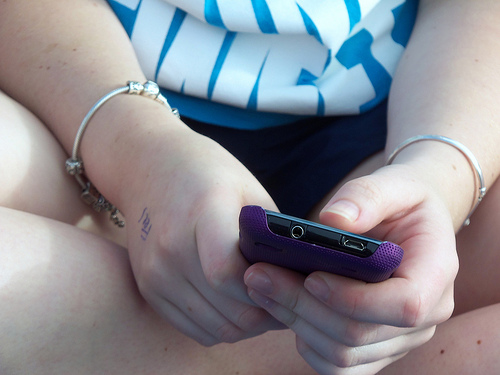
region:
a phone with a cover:
[219, 187, 411, 336]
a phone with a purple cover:
[247, 184, 426, 348]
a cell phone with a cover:
[237, 158, 447, 347]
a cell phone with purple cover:
[211, 177, 401, 322]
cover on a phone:
[232, 191, 462, 351]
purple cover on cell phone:
[232, 160, 468, 374]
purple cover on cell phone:
[229, 197, 410, 307]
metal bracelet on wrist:
[385, 115, 486, 239]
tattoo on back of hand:
[134, 202, 164, 248]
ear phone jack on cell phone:
[284, 220, 308, 242]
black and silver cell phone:
[228, 181, 411, 298]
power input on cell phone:
[338, 230, 370, 257]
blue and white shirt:
[108, 0, 427, 144]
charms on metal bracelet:
[118, 67, 170, 109]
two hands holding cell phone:
[77, 93, 490, 372]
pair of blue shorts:
[171, 96, 418, 245]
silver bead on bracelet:
[156, 93, 168, 105]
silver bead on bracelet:
[141, 78, 159, 97]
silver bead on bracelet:
[125, 78, 142, 93]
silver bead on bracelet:
[66, 158, 81, 175]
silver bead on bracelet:
[76, 186, 103, 211]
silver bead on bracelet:
[95, 198, 107, 212]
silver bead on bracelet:
[476, 187, 486, 204]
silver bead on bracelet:
[463, 218, 471, 226]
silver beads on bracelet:
[125, 75, 167, 102]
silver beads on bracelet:
[66, 156, 106, 213]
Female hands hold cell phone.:
[134, 119, 439, 370]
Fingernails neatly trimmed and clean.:
[229, 260, 357, 330]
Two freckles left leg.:
[429, 329, 499, 372]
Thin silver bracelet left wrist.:
[386, 136, 491, 232]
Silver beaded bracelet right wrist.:
[53, 75, 201, 195]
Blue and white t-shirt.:
[142, 3, 429, 103]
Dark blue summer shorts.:
[166, 90, 391, 200]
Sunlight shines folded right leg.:
[2, 90, 56, 317]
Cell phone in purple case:
[237, 202, 406, 283]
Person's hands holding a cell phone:
[124, 133, 461, 373]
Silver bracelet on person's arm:
[383, 133, 488, 228]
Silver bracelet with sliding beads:
[63, 78, 183, 228]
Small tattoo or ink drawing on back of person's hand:
[134, 205, 153, 242]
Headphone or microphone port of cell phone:
[288, 223, 305, 242]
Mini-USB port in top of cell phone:
[342, 235, 367, 252]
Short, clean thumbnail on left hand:
[324, 198, 361, 224]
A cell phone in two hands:
[120, 123, 465, 371]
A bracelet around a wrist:
[380, 125, 490, 230]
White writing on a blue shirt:
[100, 0, 420, 137]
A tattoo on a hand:
[130, 195, 160, 246]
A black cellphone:
[239, 207, 407, 277]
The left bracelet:
[50, 64, 201, 198]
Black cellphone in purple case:
[211, 196, 453, 301]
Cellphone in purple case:
[216, 195, 418, 297]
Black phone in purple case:
[228, 199, 414, 292]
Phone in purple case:
[236, 185, 407, 297]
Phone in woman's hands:
[121, 118, 463, 363]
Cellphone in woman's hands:
[118, 115, 460, 348]